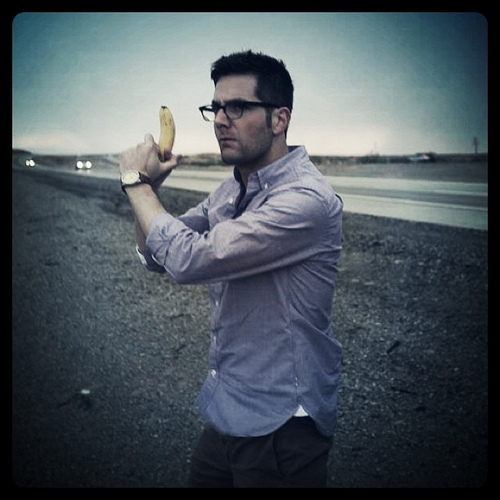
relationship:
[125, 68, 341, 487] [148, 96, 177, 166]
man holding banana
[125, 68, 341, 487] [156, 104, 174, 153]
man holding banana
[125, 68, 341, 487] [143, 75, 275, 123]
man wearing glasses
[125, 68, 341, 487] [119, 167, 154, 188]
man wearing wristwatch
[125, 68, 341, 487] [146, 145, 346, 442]
man wearing purple shirt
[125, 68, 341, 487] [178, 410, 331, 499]
man wearing pants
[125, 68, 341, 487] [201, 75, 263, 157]
man with facial expression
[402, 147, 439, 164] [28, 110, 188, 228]
car in distance